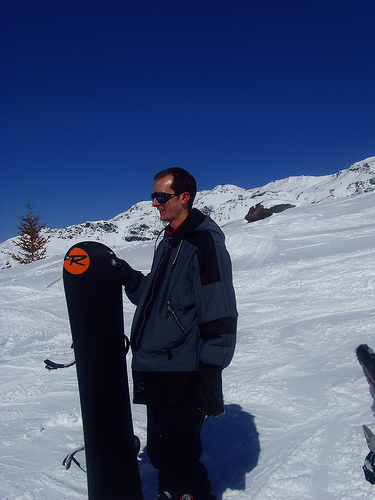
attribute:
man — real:
[117, 167, 239, 496]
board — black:
[61, 242, 146, 499]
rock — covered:
[246, 201, 299, 224]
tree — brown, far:
[15, 189, 53, 270]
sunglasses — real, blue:
[150, 189, 171, 205]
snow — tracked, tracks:
[285, 302, 341, 365]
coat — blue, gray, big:
[133, 214, 239, 372]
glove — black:
[111, 254, 143, 294]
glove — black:
[198, 364, 227, 420]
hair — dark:
[156, 166, 195, 194]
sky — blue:
[0, 2, 371, 236]